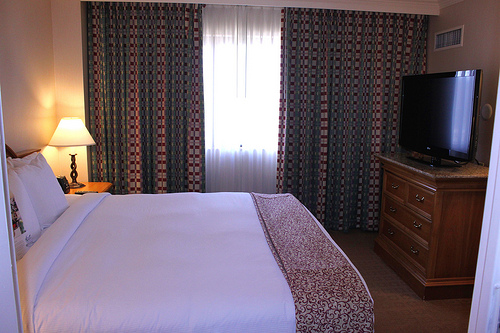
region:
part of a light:
[222, 50, 267, 117]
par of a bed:
[222, 279, 242, 311]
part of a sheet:
[214, 265, 246, 307]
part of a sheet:
[201, 263, 243, 319]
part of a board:
[388, 197, 409, 305]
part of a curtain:
[338, 152, 375, 184]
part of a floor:
[360, 234, 414, 298]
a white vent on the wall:
[433, 26, 464, 52]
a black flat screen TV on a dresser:
[400, 70, 480, 165]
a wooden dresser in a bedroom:
[372, 150, 488, 297]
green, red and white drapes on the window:
[83, 1, 426, 229]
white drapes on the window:
[200, 3, 280, 189]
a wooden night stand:
[68, 177, 111, 193]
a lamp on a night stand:
[46, 118, 96, 188]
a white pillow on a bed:
[12, 153, 69, 231]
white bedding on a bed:
[16, 192, 296, 332]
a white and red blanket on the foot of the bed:
[248, 188, 375, 331]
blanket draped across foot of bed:
[252, 194, 364, 329]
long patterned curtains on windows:
[90, 1, 411, 233]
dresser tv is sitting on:
[379, 152, 494, 289]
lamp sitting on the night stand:
[50, 122, 95, 189]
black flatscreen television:
[402, 72, 475, 168]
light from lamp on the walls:
[25, 75, 95, 178]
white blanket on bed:
[35, 177, 338, 332]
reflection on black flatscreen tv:
[450, 66, 474, 159]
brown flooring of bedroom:
[339, 222, 484, 331]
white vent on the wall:
[432, 26, 465, 46]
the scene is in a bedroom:
[23, 13, 477, 332]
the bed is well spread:
[1, 169, 369, 331]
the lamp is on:
[40, 92, 119, 213]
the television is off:
[364, 63, 499, 158]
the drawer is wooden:
[373, 165, 481, 282]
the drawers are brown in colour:
[376, 158, 475, 332]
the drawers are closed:
[377, 167, 432, 287]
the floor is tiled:
[373, 275, 416, 332]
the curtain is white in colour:
[467, 169, 499, 329]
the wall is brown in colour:
[25, 18, 65, 100]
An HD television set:
[397, 68, 484, 167]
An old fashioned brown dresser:
[372, 149, 487, 296]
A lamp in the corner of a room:
[49, 117, 94, 189]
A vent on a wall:
[433, 25, 464, 49]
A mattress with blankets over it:
[0, 153, 376, 331]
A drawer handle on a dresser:
[413, 192, 423, 202]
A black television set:
[398, 70, 480, 164]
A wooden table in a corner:
[65, 179, 111, 193]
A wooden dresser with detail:
[373, 153, 485, 298]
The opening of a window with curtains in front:
[200, 5, 279, 191]